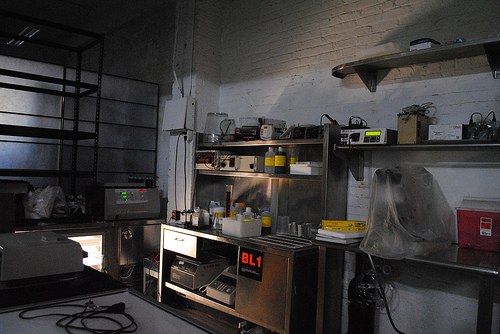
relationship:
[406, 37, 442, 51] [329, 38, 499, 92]
item on shelf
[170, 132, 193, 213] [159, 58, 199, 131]
cords plugged into power box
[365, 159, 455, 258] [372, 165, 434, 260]
tarp covering item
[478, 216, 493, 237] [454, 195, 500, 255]
caution on box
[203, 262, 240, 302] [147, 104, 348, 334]
cash register under workstation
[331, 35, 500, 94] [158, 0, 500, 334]
high shelf on brick wall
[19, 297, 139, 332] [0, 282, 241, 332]
cable on floor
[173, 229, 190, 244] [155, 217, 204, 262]
handle on drawer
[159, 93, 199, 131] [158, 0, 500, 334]
power box on brick wall